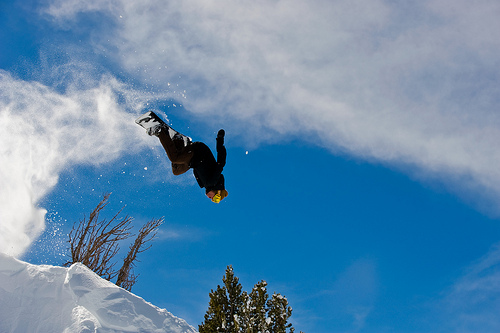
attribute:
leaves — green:
[226, 300, 266, 322]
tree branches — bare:
[65, 194, 166, 290]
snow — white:
[0, 250, 197, 331]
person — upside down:
[134, 107, 229, 202]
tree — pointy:
[189, 265, 300, 331]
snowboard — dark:
[133, 110, 189, 155]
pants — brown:
[160, 130, 198, 185]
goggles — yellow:
[209, 192, 226, 204]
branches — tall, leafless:
[56, 190, 148, 282]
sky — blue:
[0, 3, 498, 331]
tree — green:
[196, 244, 301, 331]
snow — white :
[0, 71, 74, 258]